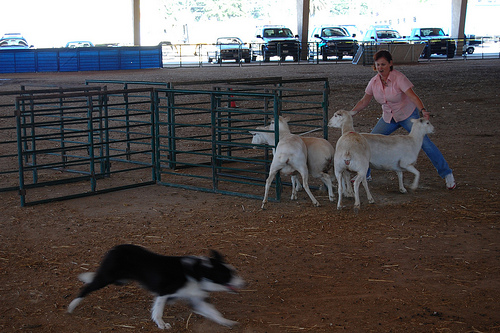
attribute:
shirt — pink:
[361, 71, 422, 123]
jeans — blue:
[367, 108, 455, 185]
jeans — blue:
[370, 111, 456, 177]